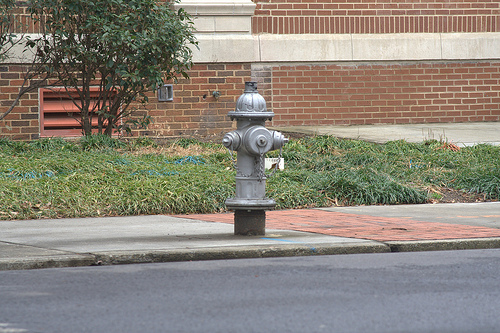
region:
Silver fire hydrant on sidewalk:
[214, 81, 286, 241]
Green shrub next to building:
[22, 2, 195, 147]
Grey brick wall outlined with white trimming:
[266, 3, 498, 115]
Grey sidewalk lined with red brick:
[274, 199, 494, 246]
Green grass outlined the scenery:
[25, 140, 188, 207]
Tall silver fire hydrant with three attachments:
[216, 74, 293, 251]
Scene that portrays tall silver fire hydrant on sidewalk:
[16, 4, 496, 309]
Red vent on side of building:
[34, 68, 129, 155]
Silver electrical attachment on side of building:
[154, 76, 184, 113]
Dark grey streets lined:
[196, 261, 416, 313]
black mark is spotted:
[387, 217, 399, 238]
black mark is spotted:
[393, 225, 405, 234]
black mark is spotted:
[396, 224, 409, 236]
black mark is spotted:
[391, 218, 410, 240]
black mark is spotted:
[399, 220, 406, 236]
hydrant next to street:
[173, 65, 325, 242]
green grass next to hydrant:
[312, 151, 377, 196]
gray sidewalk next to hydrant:
[128, 219, 175, 246]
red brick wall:
[296, 73, 351, 112]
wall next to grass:
[329, 68, 394, 118]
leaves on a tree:
[89, 18, 156, 81]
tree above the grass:
[61, 12, 176, 125]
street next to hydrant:
[268, 282, 345, 323]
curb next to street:
[322, 235, 374, 275]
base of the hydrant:
[219, 194, 277, 250]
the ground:
[262, 197, 373, 332]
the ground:
[272, 277, 319, 322]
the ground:
[332, 295, 354, 326]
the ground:
[324, 290, 379, 322]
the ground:
[281, 230, 317, 277]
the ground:
[320, 318, 360, 324]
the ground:
[305, 299, 330, 321]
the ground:
[281, 288, 308, 325]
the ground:
[328, 265, 378, 331]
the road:
[239, 276, 274, 321]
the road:
[258, 220, 307, 318]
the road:
[321, 241, 362, 307]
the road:
[326, 285, 350, 319]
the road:
[304, 286, 330, 323]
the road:
[281, 271, 315, 331]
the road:
[285, 248, 326, 305]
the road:
[286, 210, 332, 321]